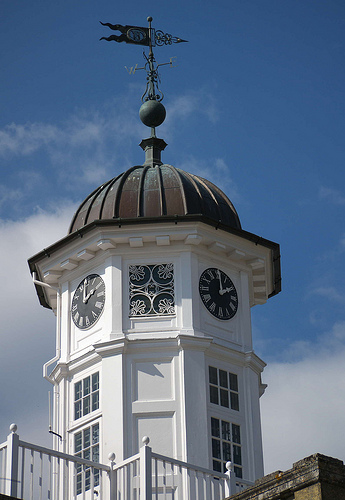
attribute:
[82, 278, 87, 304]
hand — white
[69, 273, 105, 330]
clock — black and white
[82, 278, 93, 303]
hand — white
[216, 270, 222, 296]
hand — white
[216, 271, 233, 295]
hand — white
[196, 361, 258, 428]
window — small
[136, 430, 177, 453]
ball — white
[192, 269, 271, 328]
clock — black, white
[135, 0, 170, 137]
vane — metal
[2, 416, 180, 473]
fence — white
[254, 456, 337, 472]
edge — concrete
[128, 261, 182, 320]
window — dark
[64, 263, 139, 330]
clock — black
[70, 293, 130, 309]
numbers — white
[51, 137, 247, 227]
dome — brown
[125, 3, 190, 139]
vane — green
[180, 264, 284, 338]
clock — black, white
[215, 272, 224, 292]
hand — white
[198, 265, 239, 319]
clock face — black and white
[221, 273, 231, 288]
roman numeral — white, I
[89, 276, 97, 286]
roman numeral — I, white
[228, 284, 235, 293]
roman numeral — white, II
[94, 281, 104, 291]
roman numeral — II, white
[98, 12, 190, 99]
weather vain — metal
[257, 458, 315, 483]
building edge — brick and brown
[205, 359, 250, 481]
side window — facing the shade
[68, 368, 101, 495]
windows — facing the sun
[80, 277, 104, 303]
time — 2:00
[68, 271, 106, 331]
clock face — black and white, white , black 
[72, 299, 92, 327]
numerals — ROMAN